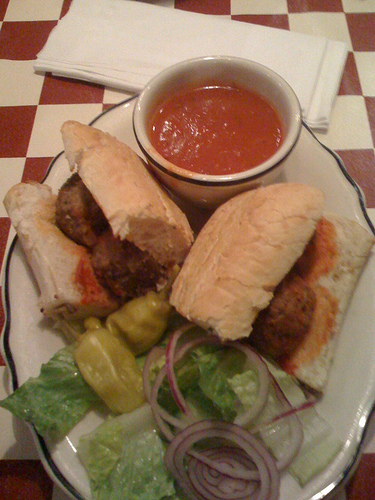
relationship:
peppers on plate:
[79, 281, 174, 412] [2, 84, 373, 497]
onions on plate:
[153, 416, 298, 498] [2, 84, 373, 497]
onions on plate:
[148, 321, 283, 429] [2, 84, 373, 497]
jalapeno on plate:
[85, 320, 133, 397] [41, 129, 348, 491]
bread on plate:
[179, 181, 360, 388] [2, 84, 373, 497]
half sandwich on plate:
[2, 125, 197, 313] [2, 84, 373, 497]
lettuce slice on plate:
[2, 334, 130, 435] [2, 84, 373, 497]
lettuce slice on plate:
[81, 333, 345, 499] [2, 84, 373, 497]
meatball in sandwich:
[264, 249, 321, 358] [189, 238, 343, 364]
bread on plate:
[203, 214, 277, 270] [311, 132, 339, 210]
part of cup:
[227, 52, 263, 85] [130, 54, 306, 213]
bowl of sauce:
[129, 48, 313, 209] [185, 89, 247, 153]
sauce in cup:
[167, 73, 271, 155] [130, 54, 306, 213]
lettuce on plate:
[1, 345, 105, 452] [2, 84, 373, 497]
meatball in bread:
[264, 249, 321, 358] [166, 180, 373, 396]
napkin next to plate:
[31, 0, 346, 132] [2, 84, 373, 497]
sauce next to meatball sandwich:
[137, 73, 286, 186] [2, 114, 371, 402]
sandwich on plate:
[2, 166, 373, 392] [2, 84, 373, 497]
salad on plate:
[1, 287, 343, 498] [2, 84, 373, 497]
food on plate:
[6, 49, 323, 482] [2, 84, 373, 497]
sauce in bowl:
[167, 73, 271, 155] [129, 48, 313, 209]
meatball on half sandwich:
[50, 169, 108, 250] [2, 125, 197, 313]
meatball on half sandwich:
[91, 227, 163, 310] [2, 125, 197, 313]